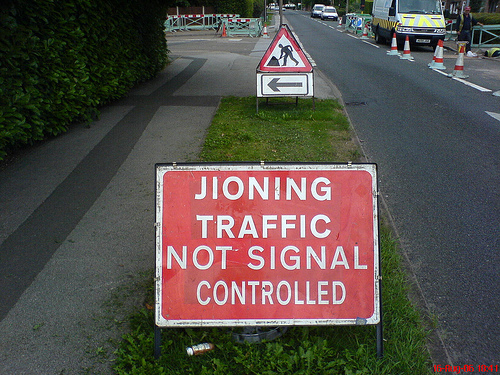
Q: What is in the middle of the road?
A: A Sign.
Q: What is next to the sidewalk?
A: Bushes.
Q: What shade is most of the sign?
A: Red.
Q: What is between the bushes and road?
A: A sidewalk.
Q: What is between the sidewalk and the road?
A: Grass.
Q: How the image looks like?
A: Cool.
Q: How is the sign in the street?
A: Red.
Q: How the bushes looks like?
A: Good.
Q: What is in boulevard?
A: Green grass.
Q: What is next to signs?
A: Grey road.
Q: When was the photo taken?
A: Daytime.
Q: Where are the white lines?
A: Street.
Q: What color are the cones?
A: Orange and white.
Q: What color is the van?
A: White and yellow.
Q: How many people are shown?
A: One.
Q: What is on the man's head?
A: Cap.